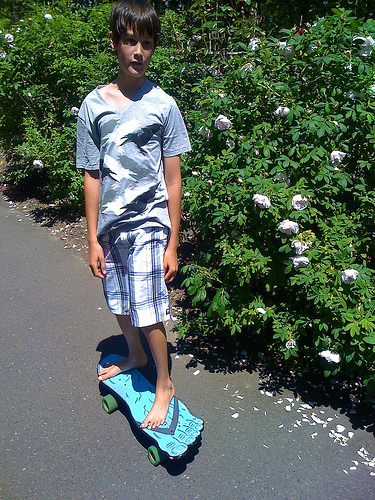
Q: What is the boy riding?
A: A skateboard.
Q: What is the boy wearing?
A: Blue and white shorts.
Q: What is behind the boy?
A: A red and white flower bush.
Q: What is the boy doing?
A: Riding a skateboard.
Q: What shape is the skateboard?
A: A foot.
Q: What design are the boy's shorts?
A: Plaid.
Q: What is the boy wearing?
A: A t-shirt and shorts.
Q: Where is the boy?
A: On a paved road.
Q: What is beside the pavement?
A: A big bush.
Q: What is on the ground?
A: Flower petals.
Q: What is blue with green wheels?
A: Skateboard.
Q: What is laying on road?
A: The petals.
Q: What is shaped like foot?
A: Blue skateboard.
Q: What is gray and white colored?
A: Shirt on boy.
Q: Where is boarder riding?
A: Paved path.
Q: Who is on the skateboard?
A: Little white boy.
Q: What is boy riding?
A: Blue foot shaped skateboard.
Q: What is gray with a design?
A: The shirt.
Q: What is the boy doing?
A: Skateboarding.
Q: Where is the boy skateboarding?
A: Driveway.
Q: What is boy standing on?
A: A skateboard.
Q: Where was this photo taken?
A: In a park.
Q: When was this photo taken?
A: In the daytime.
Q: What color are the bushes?
A: Green.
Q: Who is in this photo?
A: A boy.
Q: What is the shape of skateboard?
A: A foot.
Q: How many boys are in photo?
A: One.